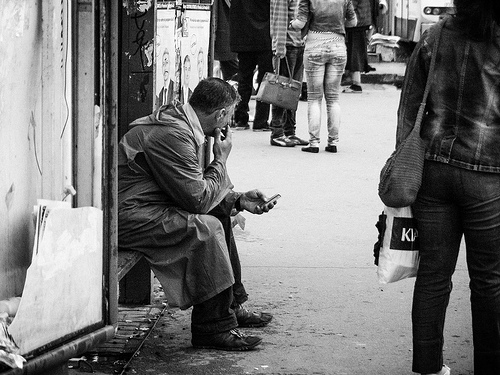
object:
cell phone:
[261, 193, 282, 211]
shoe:
[189, 328, 263, 352]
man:
[118, 77, 275, 350]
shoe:
[229, 305, 275, 328]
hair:
[189, 77, 242, 115]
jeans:
[301, 29, 348, 148]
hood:
[128, 104, 179, 127]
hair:
[443, 0, 500, 49]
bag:
[255, 55, 302, 111]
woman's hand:
[272, 44, 287, 59]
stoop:
[100, 234, 161, 314]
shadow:
[134, 336, 199, 373]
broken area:
[4, 205, 106, 362]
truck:
[0, 0, 145, 356]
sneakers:
[270, 135, 296, 148]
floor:
[91, 304, 152, 353]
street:
[0, 1, 493, 375]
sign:
[423, 6, 452, 15]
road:
[126, 54, 471, 375]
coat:
[118, 103, 238, 310]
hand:
[213, 125, 233, 157]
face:
[216, 98, 236, 138]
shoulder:
[419, 14, 454, 56]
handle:
[275, 55, 292, 78]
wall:
[153, 5, 215, 120]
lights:
[423, 6, 433, 16]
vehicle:
[381, 0, 451, 41]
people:
[285, 0, 359, 153]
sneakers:
[285, 135, 309, 146]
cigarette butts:
[129, 334, 135, 339]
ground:
[32, 83, 476, 375]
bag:
[375, 204, 420, 286]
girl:
[393, 0, 498, 374]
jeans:
[409, 161, 500, 375]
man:
[269, 0, 309, 148]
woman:
[341, 0, 381, 93]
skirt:
[345, 26, 377, 74]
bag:
[377, 16, 449, 208]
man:
[220, 0, 273, 132]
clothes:
[227, 0, 272, 53]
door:
[157, 8, 185, 115]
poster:
[154, 9, 213, 109]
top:
[294, 1, 360, 38]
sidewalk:
[277, 233, 367, 346]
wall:
[118, 2, 156, 134]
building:
[0, 0, 215, 365]